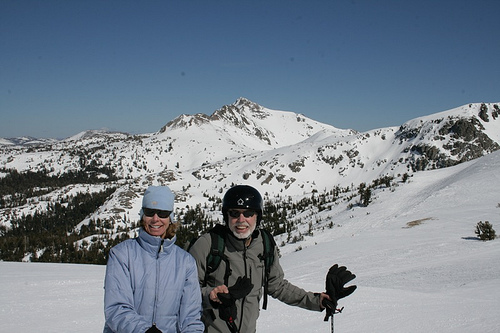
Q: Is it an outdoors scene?
A: Yes, it is outdoors.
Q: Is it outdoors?
A: Yes, it is outdoors.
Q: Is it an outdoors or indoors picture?
A: It is outdoors.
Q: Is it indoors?
A: No, it is outdoors.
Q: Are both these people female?
A: No, they are both male and female.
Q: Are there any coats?
A: Yes, there is a coat.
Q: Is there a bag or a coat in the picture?
A: Yes, there is a coat.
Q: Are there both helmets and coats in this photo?
A: Yes, there are both a coat and a helmet.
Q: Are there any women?
A: Yes, there is a woman.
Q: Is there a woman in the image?
A: Yes, there is a woman.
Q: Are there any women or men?
A: Yes, there is a woman.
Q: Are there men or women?
A: Yes, there is a woman.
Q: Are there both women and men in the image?
A: Yes, there are both a woman and a man.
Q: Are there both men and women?
A: Yes, there are both a woman and a man.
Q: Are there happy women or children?
A: Yes, there is a happy woman.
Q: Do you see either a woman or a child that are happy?
A: Yes, the woman is happy.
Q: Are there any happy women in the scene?
A: Yes, there is a happy woman.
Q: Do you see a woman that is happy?
A: Yes, there is a woman that is happy.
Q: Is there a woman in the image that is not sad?
A: Yes, there is a happy woman.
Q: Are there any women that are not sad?
A: Yes, there is a happy woman.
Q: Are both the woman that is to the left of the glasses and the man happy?
A: Yes, both the woman and the man are happy.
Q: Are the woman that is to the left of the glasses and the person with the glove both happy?
A: Yes, both the woman and the man are happy.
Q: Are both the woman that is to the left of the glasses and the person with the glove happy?
A: Yes, both the woman and the man are happy.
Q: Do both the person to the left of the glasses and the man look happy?
A: Yes, both the woman and the man are happy.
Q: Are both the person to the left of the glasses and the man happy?
A: Yes, both the woman and the man are happy.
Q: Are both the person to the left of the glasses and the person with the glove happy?
A: Yes, both the woman and the man are happy.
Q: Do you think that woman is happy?
A: Yes, the woman is happy.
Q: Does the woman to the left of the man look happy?
A: Yes, the woman is happy.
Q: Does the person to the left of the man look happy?
A: Yes, the woman is happy.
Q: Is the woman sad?
A: No, the woman is happy.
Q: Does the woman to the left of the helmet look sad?
A: No, the woman is happy.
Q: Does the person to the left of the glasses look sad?
A: No, the woman is happy.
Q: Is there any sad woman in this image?
A: No, there is a woman but she is happy.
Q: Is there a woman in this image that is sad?
A: No, there is a woman but she is happy.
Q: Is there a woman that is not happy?
A: No, there is a woman but she is happy.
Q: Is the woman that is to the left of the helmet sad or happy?
A: The woman is happy.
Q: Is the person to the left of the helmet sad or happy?
A: The woman is happy.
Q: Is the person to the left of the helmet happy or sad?
A: The woman is happy.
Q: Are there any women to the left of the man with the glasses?
A: Yes, there is a woman to the left of the man.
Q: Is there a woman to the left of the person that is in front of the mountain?
A: Yes, there is a woman to the left of the man.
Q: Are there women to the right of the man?
A: No, the woman is to the left of the man.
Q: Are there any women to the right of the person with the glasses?
A: No, the woman is to the left of the man.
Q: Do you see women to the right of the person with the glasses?
A: No, the woman is to the left of the man.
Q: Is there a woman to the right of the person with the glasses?
A: No, the woman is to the left of the man.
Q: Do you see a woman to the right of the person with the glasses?
A: No, the woman is to the left of the man.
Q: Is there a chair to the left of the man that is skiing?
A: No, there is a woman to the left of the man.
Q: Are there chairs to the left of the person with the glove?
A: No, there is a woman to the left of the man.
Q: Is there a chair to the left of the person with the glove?
A: No, there is a woman to the left of the man.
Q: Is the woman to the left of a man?
A: Yes, the woman is to the left of a man.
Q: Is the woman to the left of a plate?
A: No, the woman is to the left of a man.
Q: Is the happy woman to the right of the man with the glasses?
A: No, the woman is to the left of the man.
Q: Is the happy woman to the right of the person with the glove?
A: No, the woman is to the left of the man.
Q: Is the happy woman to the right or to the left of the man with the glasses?
A: The woman is to the left of the man.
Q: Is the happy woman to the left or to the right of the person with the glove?
A: The woman is to the left of the man.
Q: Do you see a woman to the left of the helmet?
A: Yes, there is a woman to the left of the helmet.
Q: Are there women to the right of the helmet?
A: No, the woman is to the left of the helmet.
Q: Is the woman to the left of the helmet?
A: Yes, the woman is to the left of the helmet.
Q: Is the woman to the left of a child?
A: No, the woman is to the left of the helmet.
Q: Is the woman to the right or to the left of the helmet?
A: The woman is to the left of the helmet.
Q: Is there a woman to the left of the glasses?
A: Yes, there is a woman to the left of the glasses.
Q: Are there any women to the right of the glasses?
A: No, the woman is to the left of the glasses.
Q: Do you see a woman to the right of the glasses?
A: No, the woman is to the left of the glasses.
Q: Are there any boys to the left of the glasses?
A: No, there is a woman to the left of the glasses.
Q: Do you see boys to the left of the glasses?
A: No, there is a woman to the left of the glasses.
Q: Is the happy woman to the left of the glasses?
A: Yes, the woman is to the left of the glasses.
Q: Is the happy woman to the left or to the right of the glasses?
A: The woman is to the left of the glasses.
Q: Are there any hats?
A: Yes, there is a hat.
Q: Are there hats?
A: Yes, there is a hat.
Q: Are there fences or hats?
A: Yes, there is a hat.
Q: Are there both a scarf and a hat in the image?
A: No, there is a hat but no scarves.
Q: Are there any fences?
A: No, there are no fences.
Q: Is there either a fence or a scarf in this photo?
A: No, there are no fences or scarves.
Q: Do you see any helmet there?
A: Yes, there is a helmet.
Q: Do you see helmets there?
A: Yes, there is a helmet.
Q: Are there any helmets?
A: Yes, there is a helmet.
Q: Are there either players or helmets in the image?
A: Yes, there is a helmet.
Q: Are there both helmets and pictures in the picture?
A: No, there is a helmet but no pictures.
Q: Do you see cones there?
A: No, there are no cones.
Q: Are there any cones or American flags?
A: No, there are no cones or American flags.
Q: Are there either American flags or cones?
A: No, there are no cones or American flags.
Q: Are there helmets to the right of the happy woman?
A: Yes, there is a helmet to the right of the woman.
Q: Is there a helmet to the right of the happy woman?
A: Yes, there is a helmet to the right of the woman.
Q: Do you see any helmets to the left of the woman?
A: No, the helmet is to the right of the woman.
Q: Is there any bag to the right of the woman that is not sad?
A: No, there is a helmet to the right of the woman.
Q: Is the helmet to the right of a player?
A: No, the helmet is to the right of the woman.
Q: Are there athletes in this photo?
A: No, there are no athletes.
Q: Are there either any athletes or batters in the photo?
A: No, there are no athletes or batters.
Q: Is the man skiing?
A: Yes, the man is skiing.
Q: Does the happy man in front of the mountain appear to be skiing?
A: Yes, the man is skiing.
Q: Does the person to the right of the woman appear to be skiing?
A: Yes, the man is skiing.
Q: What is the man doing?
A: The man is skiing.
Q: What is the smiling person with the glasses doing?
A: The man is skiing.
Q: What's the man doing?
A: The man is skiing.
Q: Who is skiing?
A: The man is skiing.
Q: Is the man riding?
A: No, the man is skiing.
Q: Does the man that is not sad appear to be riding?
A: No, the man is skiing.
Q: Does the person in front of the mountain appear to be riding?
A: No, the man is skiing.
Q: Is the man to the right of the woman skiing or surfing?
A: The man is skiing.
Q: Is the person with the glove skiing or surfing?
A: The man is skiing.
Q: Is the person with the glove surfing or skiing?
A: The man is skiing.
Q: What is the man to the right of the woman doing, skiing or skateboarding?
A: The man is skiing.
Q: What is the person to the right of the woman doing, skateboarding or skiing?
A: The man is skiing.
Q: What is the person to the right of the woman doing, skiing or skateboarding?
A: The man is skiing.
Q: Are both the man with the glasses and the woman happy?
A: Yes, both the man and the woman are happy.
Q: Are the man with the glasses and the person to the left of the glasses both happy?
A: Yes, both the man and the woman are happy.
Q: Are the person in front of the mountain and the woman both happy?
A: Yes, both the man and the woman are happy.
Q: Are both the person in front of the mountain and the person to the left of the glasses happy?
A: Yes, both the man and the woman are happy.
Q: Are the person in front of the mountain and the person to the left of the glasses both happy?
A: Yes, both the man and the woman are happy.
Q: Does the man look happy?
A: Yes, the man is happy.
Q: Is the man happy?
A: Yes, the man is happy.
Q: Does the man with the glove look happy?
A: Yes, the man is happy.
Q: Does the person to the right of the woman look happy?
A: Yes, the man is happy.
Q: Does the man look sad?
A: No, the man is happy.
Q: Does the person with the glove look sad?
A: No, the man is happy.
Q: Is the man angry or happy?
A: The man is happy.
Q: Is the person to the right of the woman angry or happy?
A: The man is happy.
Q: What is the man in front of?
A: The man is in front of the mountain.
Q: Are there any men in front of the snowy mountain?
A: Yes, there is a man in front of the mountain.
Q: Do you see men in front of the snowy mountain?
A: Yes, there is a man in front of the mountain.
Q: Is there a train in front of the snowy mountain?
A: No, there is a man in front of the mountain.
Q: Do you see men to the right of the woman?
A: Yes, there is a man to the right of the woman.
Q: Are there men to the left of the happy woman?
A: No, the man is to the right of the woman.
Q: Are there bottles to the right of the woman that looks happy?
A: No, there is a man to the right of the woman.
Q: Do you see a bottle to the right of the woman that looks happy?
A: No, there is a man to the right of the woman.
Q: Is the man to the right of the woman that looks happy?
A: Yes, the man is to the right of the woman.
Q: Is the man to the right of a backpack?
A: No, the man is to the right of the woman.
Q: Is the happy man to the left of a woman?
A: No, the man is to the right of a woman.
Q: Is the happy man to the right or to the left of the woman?
A: The man is to the right of the woman.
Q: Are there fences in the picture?
A: No, there are no fences.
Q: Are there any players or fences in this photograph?
A: No, there are no fences or players.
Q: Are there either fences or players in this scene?
A: No, there are no fences or players.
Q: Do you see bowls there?
A: No, there are no bowls.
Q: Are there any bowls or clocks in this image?
A: No, there are no bowls or clocks.